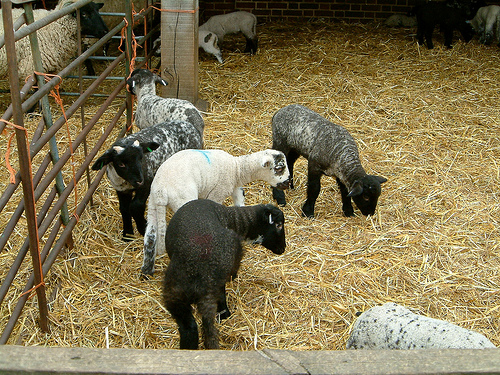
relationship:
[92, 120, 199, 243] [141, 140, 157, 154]
sheep has ear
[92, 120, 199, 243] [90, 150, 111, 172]
sheep has ear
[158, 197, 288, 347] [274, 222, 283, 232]
sheep has eye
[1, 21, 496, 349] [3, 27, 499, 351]
hay on ground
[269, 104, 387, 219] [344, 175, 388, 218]
baby goat has head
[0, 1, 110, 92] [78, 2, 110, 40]
sheep has face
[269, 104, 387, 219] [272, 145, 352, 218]
baby goat has legs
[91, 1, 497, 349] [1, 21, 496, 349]
goats are standing in hay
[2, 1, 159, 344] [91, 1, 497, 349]
fence near goats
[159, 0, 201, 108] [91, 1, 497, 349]
post behind goats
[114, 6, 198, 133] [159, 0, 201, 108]
string tied to post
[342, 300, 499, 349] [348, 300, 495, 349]
baby goat has spots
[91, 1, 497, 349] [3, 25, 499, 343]
goats are in pen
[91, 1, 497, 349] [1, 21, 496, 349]
goats are eating hay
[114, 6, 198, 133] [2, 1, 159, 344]
string on fence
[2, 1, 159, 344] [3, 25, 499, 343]
fence in pen